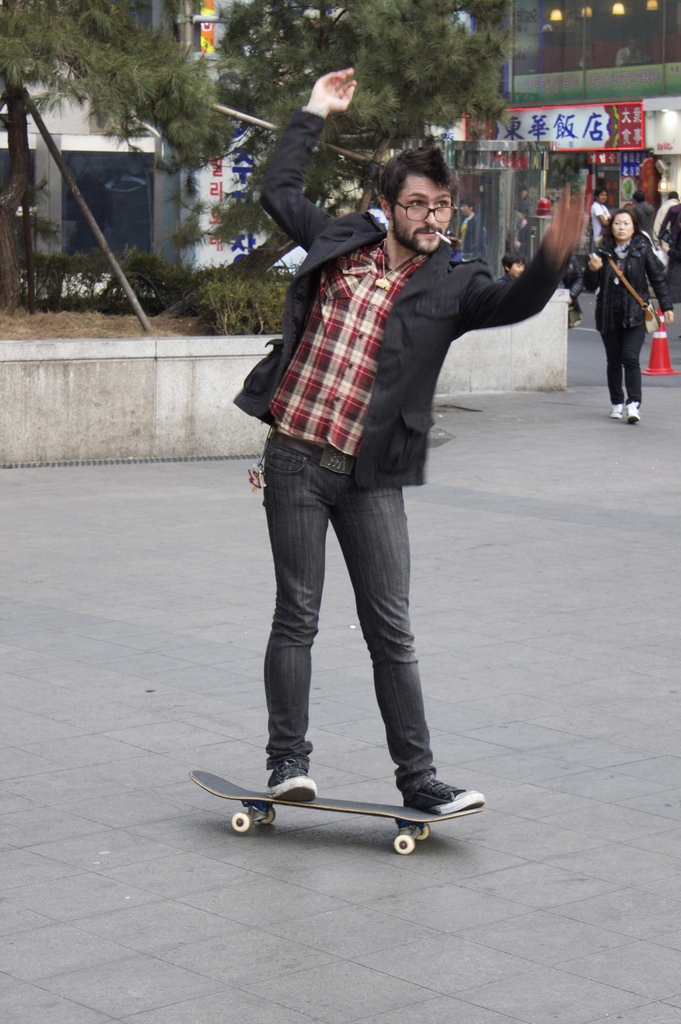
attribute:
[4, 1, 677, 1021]
picture — outdoors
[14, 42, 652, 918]
picture — taken outdoors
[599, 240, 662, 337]
brown purse — brown 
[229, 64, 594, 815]
man — young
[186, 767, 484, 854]
skateboard — black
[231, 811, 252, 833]
wheel — white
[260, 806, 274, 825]
wheel — white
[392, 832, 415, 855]
wheel — white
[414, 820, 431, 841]
wheel — white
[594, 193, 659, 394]
woman — Asian 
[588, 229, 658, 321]
jacket — black 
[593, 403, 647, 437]
shoes — white 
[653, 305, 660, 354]
cone — white traffic, Orange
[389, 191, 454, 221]
eyeglasses — Black 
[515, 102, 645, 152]
sign — Red, white, and blue , Asian text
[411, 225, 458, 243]
mouth — skateboarder's , Cigarette 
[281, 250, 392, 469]
shirt — Red, brown and white plaid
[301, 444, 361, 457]
buckle — Large rectangular belt 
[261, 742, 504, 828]
shoes — Black and white tennis 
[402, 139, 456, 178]
hair — dark 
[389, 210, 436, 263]
hair — dark facial 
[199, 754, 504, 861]
skateboard — White wheels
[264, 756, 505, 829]
shoes — black and white 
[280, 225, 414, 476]
shirt — plaid 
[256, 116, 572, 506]
jacket — dark 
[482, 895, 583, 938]
tile — gray stone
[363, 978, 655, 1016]
tile — gray stone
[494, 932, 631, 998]
tile — gray stone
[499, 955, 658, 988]
tile — gray stone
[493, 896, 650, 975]
tile — gray stone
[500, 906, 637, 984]
tile — gray stone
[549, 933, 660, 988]
tile — gray stone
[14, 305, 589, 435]
box — large grey concrete planting 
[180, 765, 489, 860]
skateboard — wooden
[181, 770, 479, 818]
top — textured, black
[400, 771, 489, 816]
skater shoe — black, white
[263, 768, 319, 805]
skater shoe — white, black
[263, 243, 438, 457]
shirt — red, white, plaid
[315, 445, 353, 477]
buckle — square, bronze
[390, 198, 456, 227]
glasses — black, thin framed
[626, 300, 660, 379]
traffic cone — orange, white